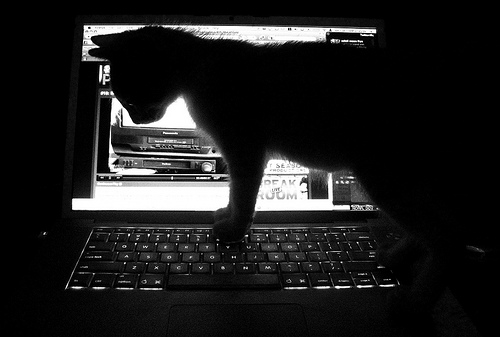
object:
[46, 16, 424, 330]
laptop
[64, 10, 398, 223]
monitor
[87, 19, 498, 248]
cat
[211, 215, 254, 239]
left paw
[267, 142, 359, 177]
stomach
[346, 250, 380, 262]
button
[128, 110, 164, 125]
mouth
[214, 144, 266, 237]
leg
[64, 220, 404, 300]
keyboard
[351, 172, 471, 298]
hind leg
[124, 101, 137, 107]
eye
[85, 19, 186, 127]
head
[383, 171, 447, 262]
leg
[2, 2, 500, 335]
room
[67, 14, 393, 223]
screen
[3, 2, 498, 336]
image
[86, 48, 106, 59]
ear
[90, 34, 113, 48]
ear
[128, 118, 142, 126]
nose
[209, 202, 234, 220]
paw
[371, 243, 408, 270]
paw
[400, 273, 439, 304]
paw